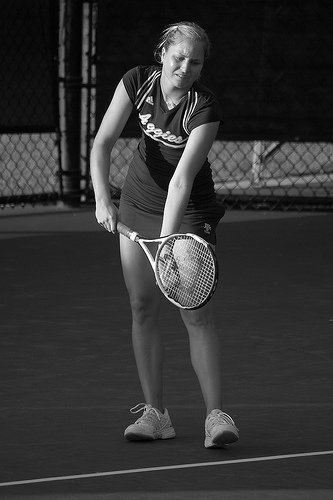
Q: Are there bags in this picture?
A: No, there are no bags.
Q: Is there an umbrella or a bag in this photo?
A: No, there are no bags or umbrellas.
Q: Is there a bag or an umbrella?
A: No, there are no bags or umbrellas.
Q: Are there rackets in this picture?
A: Yes, there is a racket.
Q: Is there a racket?
A: Yes, there is a racket.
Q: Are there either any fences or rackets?
A: Yes, there is a racket.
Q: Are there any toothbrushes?
A: No, there are no toothbrushes.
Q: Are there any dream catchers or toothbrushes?
A: No, there are no toothbrushes or dream catchers.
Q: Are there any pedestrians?
A: No, there are no pedestrians.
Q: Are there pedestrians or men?
A: No, there are no pedestrians or men.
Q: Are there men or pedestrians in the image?
A: No, there are no pedestrians or men.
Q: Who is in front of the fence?
A: The girl is in front of the fence.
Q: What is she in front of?
A: The girl is in front of the fence.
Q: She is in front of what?
A: The girl is in front of the fence.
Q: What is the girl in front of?
A: The girl is in front of the fence.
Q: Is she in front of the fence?
A: Yes, the girl is in front of the fence.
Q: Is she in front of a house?
A: No, the girl is in front of the fence.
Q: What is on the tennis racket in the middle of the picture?
A: The logo is on the tennis racket.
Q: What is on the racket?
A: The logo is on the tennis racket.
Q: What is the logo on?
A: The logo is on the tennis racket.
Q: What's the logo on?
A: The logo is on the tennis racket.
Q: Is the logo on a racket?
A: Yes, the logo is on a racket.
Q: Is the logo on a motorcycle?
A: No, the logo is on a racket.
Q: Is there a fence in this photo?
A: Yes, there is a fence.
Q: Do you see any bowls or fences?
A: Yes, there is a fence.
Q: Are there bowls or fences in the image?
A: Yes, there is a fence.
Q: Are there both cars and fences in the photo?
A: No, there is a fence but no cars.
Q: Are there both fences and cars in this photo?
A: No, there is a fence but no cars.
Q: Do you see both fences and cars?
A: No, there is a fence but no cars.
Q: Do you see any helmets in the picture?
A: No, there are no helmets.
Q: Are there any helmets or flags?
A: No, there are no helmets or flags.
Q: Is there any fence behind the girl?
A: Yes, there is a fence behind the girl.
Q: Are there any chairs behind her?
A: No, there is a fence behind the girl.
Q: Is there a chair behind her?
A: No, there is a fence behind the girl.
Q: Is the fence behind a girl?
A: Yes, the fence is behind a girl.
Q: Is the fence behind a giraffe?
A: No, the fence is behind a girl.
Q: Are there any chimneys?
A: No, there are no chimneys.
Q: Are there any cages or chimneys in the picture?
A: No, there are no chimneys or cages.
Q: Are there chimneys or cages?
A: No, there are no chimneys or cages.